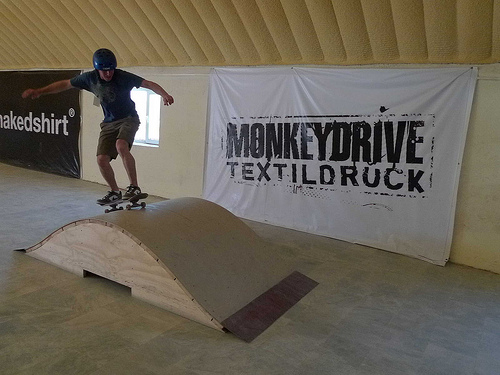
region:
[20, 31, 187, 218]
the man is skateboarding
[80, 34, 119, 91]
the helmet is blue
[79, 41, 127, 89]
the helmet is blue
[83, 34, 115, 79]
the helmet is blue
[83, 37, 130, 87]
the helmet is blue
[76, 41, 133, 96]
the helmet is blue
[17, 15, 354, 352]
man riding a skateboard over ramp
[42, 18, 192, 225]
man riding a skateboard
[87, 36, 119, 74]
man wearing a helmet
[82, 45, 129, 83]
man wearing a blue helmet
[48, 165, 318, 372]
large wooden skate ramp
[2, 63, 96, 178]
large black banner on wall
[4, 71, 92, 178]
black banner with white letters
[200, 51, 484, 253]
large white banner with black letters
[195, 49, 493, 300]
large banner on wall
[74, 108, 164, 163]
man wearing khaki shorts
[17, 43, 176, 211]
young man skateboarding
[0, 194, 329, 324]
wooden ramp on floor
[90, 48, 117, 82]
blue hard helmet on young man's head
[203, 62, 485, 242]
white banner with black lettering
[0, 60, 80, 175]
black banner with white lettering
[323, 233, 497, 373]
gray tile floor next to off-white wall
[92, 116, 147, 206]
short pants with muscular legs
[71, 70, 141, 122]
man is wearing blue short-sleeved shirt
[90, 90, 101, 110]
white tag attached to blue shirt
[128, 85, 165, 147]
window letting in sunlight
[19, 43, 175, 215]
skateboarder on a skateboard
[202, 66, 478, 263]
big white signboard with black letters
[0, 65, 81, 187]
big black signboard with white letters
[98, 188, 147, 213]
black skateboard of boy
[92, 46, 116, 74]
blue helmet of skateboarder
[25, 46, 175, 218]
skateboarder wearing blue t-shirt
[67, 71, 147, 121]
blue t-shirt of skateboarder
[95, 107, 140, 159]
brown pants of skateboarder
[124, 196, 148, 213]
two small front wheels of skateboard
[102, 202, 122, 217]
two small back wheels of skateboard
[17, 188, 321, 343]
Ramp on the floor.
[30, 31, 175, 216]
Man skateboarding on the ramp.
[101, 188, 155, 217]
Skateboard under the feet.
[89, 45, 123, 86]
Helmet on the head.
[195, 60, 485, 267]
White sign on the wall.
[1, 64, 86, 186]
Black sign on the wall.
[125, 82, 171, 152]
Window in the wall.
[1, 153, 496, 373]
Concrete floor covering the surface.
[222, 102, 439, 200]
black writing on the sign.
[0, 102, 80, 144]
White lettering on the sign.